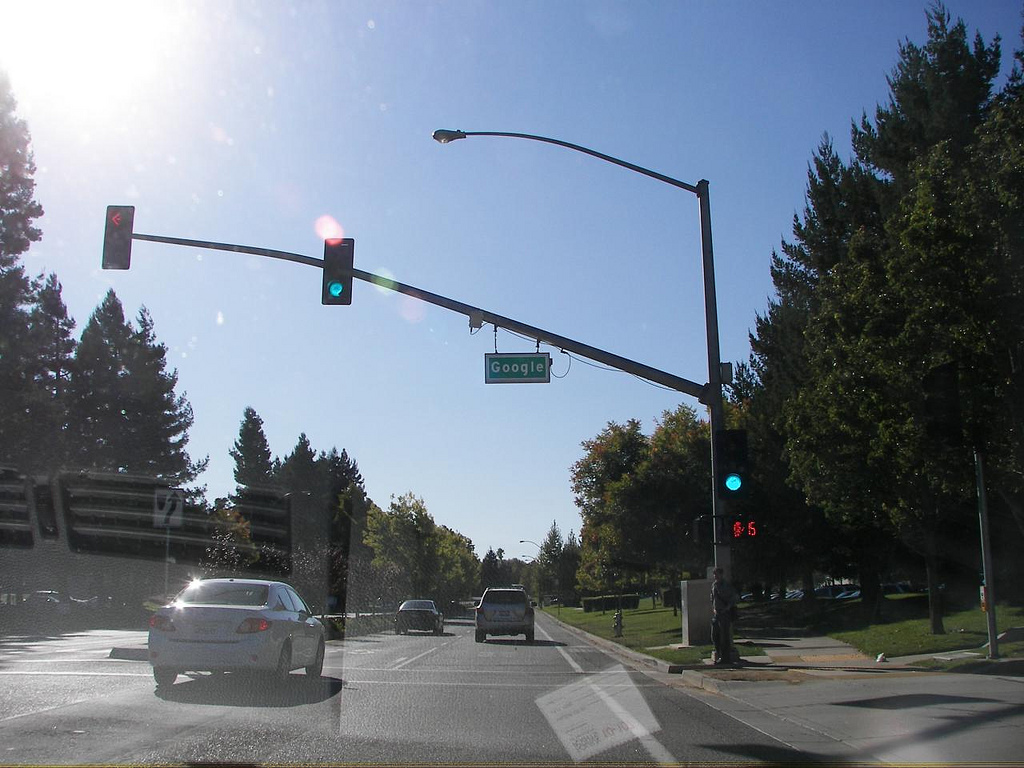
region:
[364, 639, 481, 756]
a view of road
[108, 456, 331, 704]
a view of car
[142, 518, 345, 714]
a car in road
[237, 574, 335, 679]
a view of lights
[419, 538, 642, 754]
a van in road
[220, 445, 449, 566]
a view of trees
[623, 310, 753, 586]
a view of pole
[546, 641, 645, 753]
a view of lines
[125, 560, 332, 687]
The white car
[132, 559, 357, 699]
A white vehicle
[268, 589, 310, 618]
The side windows on the white car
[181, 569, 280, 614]
The back windshield of the white car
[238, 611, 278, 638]
The right headlight of the white car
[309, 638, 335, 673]
The front tire of the white car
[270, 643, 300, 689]
The back tire of the white car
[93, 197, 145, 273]
The black traffic light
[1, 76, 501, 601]
The forest of trees to the left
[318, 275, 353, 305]
Green light illuminated on traffic signal.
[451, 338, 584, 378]
Green street sign attached to pole.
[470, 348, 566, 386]
White letters on green sign.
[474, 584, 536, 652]
SUV driving on road.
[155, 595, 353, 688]
White car driving on road.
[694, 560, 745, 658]
Person standing on corner of street.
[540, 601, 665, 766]
White line marking edge of road.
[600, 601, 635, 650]
Fire hydrant on grass.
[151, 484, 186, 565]
Black and white sign attached to pole.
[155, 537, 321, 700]
white car on road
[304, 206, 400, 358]
green traffic signal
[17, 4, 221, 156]
yellow sun in sky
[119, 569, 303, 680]
car on road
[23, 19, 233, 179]
yellow sun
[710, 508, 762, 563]
red signal light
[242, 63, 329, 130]
white clouds in blue sky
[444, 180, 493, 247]
white clouds in blue sky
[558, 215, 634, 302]
white clouds in blue sky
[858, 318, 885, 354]
green leaves on the tree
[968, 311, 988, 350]
green leaves on the tree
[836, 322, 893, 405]
green leaves on the tree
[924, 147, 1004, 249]
green leaves on the tree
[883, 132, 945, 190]
green leaves on the tree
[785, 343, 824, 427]
green leaves on the tree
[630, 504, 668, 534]
green leaves on the tree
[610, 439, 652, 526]
green leaves on the tree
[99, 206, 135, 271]
an electric traffic signal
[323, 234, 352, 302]
an electric traffic signal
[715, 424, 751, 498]
an electric traffic signal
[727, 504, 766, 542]
a do not walk signal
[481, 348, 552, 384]
a street name sign